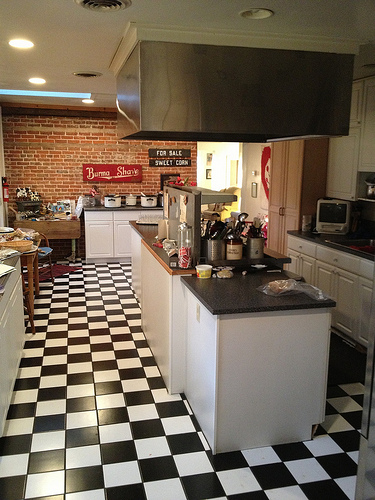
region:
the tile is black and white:
[177, 468, 192, 480]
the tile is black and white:
[193, 461, 198, 476]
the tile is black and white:
[187, 464, 202, 485]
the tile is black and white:
[197, 466, 205, 484]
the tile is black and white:
[192, 461, 203, 492]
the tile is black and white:
[193, 475, 206, 490]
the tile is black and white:
[192, 473, 204, 484]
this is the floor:
[68, 296, 130, 443]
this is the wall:
[23, 130, 78, 177]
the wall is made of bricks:
[23, 135, 71, 181]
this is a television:
[309, 199, 348, 230]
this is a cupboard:
[272, 148, 310, 190]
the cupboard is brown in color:
[276, 157, 305, 185]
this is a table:
[23, 252, 39, 306]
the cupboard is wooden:
[270, 160, 292, 196]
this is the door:
[203, 157, 245, 193]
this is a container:
[195, 259, 210, 279]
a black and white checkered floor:
[1, 293, 151, 498]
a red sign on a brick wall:
[69, 156, 147, 182]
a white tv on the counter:
[314, 189, 353, 238]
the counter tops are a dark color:
[189, 283, 256, 314]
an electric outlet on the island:
[190, 302, 203, 323]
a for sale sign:
[146, 146, 195, 158]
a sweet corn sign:
[147, 159, 190, 167]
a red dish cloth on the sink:
[346, 241, 373, 252]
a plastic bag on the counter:
[258, 275, 320, 300]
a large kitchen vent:
[108, 43, 370, 149]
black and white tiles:
[44, 323, 123, 410]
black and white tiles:
[69, 360, 144, 450]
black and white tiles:
[15, 366, 106, 464]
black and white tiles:
[68, 386, 135, 487]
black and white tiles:
[88, 349, 130, 467]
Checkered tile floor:
[71, 319, 129, 435]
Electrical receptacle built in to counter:
[187, 298, 206, 326]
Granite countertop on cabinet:
[183, 275, 338, 314]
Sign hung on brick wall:
[76, 155, 144, 185]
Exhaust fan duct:
[111, 82, 352, 143]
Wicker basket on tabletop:
[0, 240, 42, 253]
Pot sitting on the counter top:
[101, 193, 123, 210]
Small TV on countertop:
[311, 198, 356, 236]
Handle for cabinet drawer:
[325, 256, 343, 265]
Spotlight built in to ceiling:
[5, 33, 37, 56]